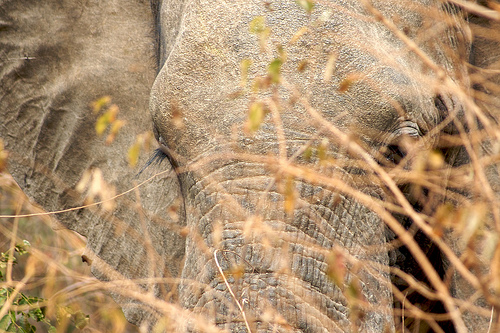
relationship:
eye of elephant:
[375, 112, 439, 163] [81, 28, 479, 324]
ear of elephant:
[4, 49, 161, 222] [81, 28, 479, 324]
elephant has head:
[81, 28, 479, 324] [118, 45, 435, 207]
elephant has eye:
[81, 28, 479, 324] [375, 112, 439, 163]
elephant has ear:
[81, 28, 479, 324] [4, 49, 161, 222]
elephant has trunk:
[81, 28, 479, 324] [132, 150, 411, 327]